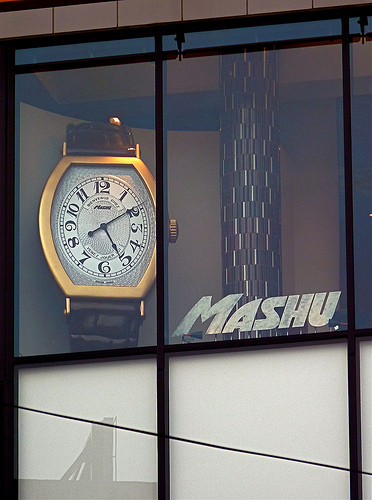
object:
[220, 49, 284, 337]
column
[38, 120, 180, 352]
watch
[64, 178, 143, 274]
numbers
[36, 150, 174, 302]
clock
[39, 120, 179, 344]
large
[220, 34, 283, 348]
pole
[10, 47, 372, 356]
room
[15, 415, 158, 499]
reflection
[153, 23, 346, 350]
window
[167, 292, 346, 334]
name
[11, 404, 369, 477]
wire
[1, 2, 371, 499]
building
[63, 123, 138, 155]
strap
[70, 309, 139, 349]
strap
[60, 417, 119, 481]
billboard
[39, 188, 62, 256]
gold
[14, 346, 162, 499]
window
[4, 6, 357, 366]
frame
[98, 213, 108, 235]
black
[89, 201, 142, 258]
hand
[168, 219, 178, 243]
knob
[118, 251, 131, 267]
5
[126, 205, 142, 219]
2